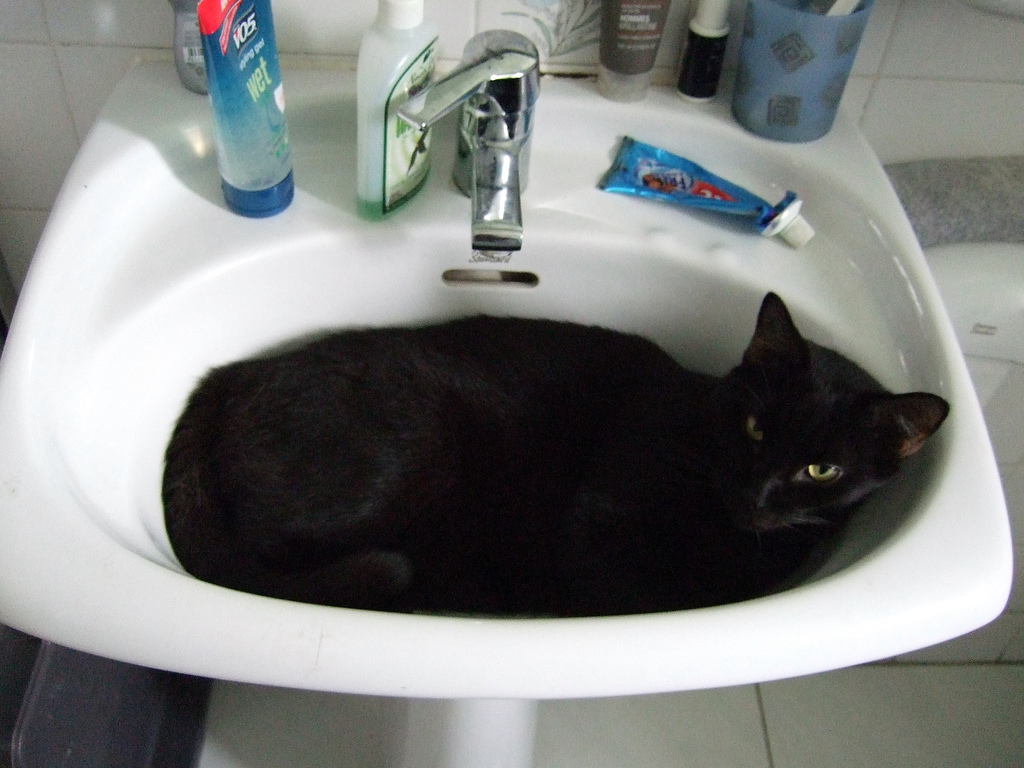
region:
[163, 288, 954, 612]
Black cat with yellow eyes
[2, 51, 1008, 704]
White bathroom sink with a cat in it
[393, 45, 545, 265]
A chrome bathroom faucet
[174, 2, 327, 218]
A blue tube of hair gel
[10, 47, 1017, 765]
A white pedestal sink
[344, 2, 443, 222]
A nearly empty bottle of green mouthwash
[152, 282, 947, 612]
A black cat resting in a sink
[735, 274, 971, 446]
Cat has black ears.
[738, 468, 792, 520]
Cat has black nose.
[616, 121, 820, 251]
Tube of toothpaste sitting on sink.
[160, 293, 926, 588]
Black cat laying in bowl of sink.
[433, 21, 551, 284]
Silver faucet on sink.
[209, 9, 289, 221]
Hair gel sitting on side of sink.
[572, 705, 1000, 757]
White tiles on floor in room.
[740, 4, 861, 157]
Blue cup sitting on sink.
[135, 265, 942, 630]
A black cat.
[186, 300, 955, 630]
A cat curled up.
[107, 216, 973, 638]
A cat in a bathroom sink.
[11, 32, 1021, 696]
A white bathroom sink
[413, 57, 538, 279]
A silver sink faucet.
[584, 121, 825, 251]
A blue and white tube of toothpaste.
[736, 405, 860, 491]
Green eyes on a cat.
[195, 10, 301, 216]
A tube of hair gel.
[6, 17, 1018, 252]
White tiles on the wall.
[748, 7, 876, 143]
A blue cup with designs on it.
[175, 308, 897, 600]
The black cat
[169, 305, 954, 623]
A black cat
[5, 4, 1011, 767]
a white restroom sink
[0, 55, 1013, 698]
black cat sitting in sink basin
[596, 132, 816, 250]
small tube of toothpaste that is mostly flattened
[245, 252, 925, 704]
a cat in the sink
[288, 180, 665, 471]
a black cat in the sink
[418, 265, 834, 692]
cat in the white sink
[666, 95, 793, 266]
toothpaste on the sink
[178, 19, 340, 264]
bottle on the sink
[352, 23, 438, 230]
bottle on the sink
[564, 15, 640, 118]
bottle on the sink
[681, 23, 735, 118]
bottle on the sink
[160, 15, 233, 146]
bottle on the sink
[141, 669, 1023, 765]
The tiled floor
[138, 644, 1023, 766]
A tiled floor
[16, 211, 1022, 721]
The white sink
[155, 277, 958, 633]
A black cat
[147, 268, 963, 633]
The black cat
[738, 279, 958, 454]
The ears of the cat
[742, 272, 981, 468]
A set of ears on the cat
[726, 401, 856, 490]
The eyes on the cat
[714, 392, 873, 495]
A set of eyes on the cat